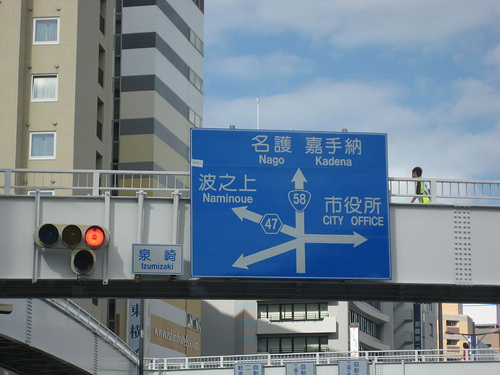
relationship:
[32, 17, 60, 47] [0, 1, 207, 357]
window on building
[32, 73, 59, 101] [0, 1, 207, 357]
window on building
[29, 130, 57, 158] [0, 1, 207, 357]
window on building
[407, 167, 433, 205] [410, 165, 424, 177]
man has head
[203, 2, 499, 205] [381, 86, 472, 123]
sky have a part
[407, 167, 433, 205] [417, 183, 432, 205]
man wearing jacket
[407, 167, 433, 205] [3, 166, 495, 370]
man across bridge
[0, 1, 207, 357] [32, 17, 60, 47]
building have window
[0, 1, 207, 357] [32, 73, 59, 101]
building have window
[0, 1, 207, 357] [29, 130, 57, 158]
building have window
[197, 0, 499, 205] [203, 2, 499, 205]
cloud against sky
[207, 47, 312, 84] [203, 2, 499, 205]
cloud against sky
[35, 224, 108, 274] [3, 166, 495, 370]
traffic light on bridge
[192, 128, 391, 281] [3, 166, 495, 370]
street sign on bridge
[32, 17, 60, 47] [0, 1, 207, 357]
window in building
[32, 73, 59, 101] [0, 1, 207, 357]
window in building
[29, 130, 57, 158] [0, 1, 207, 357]
window in building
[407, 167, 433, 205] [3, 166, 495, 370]
man on bridge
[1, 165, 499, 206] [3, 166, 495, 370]
rail on bridge